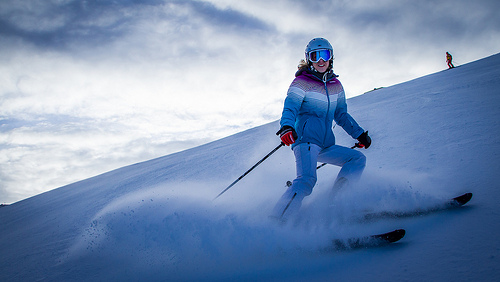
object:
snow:
[3, 220, 186, 281]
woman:
[268, 36, 374, 229]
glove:
[354, 130, 372, 150]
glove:
[274, 124, 298, 146]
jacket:
[278, 70, 366, 151]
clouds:
[1, 1, 500, 205]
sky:
[1, 1, 498, 212]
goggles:
[308, 48, 333, 63]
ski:
[308, 229, 410, 251]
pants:
[269, 142, 368, 227]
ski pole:
[283, 140, 369, 190]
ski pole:
[209, 141, 285, 202]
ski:
[360, 192, 474, 221]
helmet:
[305, 37, 334, 65]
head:
[304, 37, 335, 74]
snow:
[133, 187, 464, 271]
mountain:
[3, 50, 500, 281]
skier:
[445, 51, 455, 70]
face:
[312, 59, 329, 72]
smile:
[317, 64, 325, 67]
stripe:
[289, 86, 344, 104]